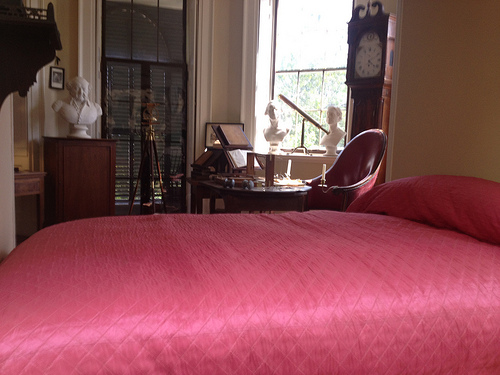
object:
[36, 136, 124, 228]
stand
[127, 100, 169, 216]
telescope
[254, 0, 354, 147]
window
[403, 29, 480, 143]
wall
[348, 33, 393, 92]
clock face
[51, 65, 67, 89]
small fame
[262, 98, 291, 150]
statute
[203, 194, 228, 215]
ground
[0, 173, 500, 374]
bed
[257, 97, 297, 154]
busts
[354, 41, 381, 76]
white square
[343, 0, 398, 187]
grandfather clock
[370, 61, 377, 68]
hands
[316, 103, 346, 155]
bust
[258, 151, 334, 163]
wooden sill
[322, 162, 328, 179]
white candle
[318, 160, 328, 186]
candle holder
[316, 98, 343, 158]
statue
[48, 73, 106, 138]
man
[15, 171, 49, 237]
nightstand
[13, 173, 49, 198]
drawer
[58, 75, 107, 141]
bust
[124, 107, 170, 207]
tripod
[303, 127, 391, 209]
chair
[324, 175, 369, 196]
arm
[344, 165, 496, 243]
pillow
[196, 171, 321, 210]
table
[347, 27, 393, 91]
clock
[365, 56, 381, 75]
6;22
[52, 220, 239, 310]
design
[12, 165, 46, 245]
stand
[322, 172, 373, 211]
arm rest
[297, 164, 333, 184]
arm rest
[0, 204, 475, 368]
blanket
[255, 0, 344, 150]
sun